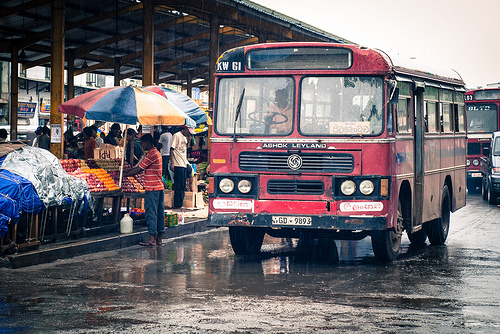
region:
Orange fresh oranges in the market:
[95, 168, 117, 188]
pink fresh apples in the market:
[84, 174, 105, 191]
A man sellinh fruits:
[135, 133, 164, 253]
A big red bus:
[211, 52, 443, 237]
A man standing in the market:
[172, 126, 194, 210]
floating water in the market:
[179, 260, 313, 322]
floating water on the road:
[369, 261, 457, 331]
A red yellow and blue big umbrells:
[64, 84, 208, 132]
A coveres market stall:
[0, 144, 82, 201]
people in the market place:
[78, 126, 125, 153]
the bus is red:
[370, 148, 398, 183]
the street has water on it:
[175, 245, 235, 299]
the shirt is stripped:
[148, 154, 159, 179]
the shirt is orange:
[146, 161, 158, 180]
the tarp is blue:
[8, 185, 25, 202]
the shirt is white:
[176, 137, 184, 157]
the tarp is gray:
[32, 163, 56, 185]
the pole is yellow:
[49, 71, 64, 96]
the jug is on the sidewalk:
[115, 211, 132, 236]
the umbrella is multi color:
[83, 82, 162, 122]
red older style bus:
[202, 38, 472, 268]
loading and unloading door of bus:
[408, 79, 430, 234]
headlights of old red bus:
[205, 170, 390, 204]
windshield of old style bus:
[207, 68, 389, 150]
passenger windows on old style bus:
[391, 72, 469, 139]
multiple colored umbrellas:
[55, 80, 215, 188]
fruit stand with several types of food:
[53, 153, 144, 227]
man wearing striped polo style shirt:
[127, 132, 171, 249]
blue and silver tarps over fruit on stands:
[0, 143, 94, 260]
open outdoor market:
[2, 0, 387, 269]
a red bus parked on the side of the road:
[213, 35, 473, 275]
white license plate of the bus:
[261, 211, 313, 230]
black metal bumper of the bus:
[201, 210, 376, 243]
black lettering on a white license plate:
[266, 215, 314, 227]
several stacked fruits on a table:
[75, 157, 150, 198]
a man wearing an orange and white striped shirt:
[138, 147, 168, 190]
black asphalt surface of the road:
[150, 258, 320, 323]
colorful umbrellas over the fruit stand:
[81, 77, 202, 129]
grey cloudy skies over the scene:
[406, 5, 472, 52]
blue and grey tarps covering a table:
[6, 135, 71, 215]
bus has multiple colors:
[195, 17, 493, 264]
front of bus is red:
[200, 26, 408, 260]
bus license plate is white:
[254, 203, 331, 238]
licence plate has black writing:
[259, 207, 327, 240]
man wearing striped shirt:
[120, 132, 172, 197]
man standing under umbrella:
[55, 62, 207, 261]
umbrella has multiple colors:
[47, 57, 217, 177]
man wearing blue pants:
[128, 175, 175, 247]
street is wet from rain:
[47, 247, 336, 332]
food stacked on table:
[52, 138, 173, 213]